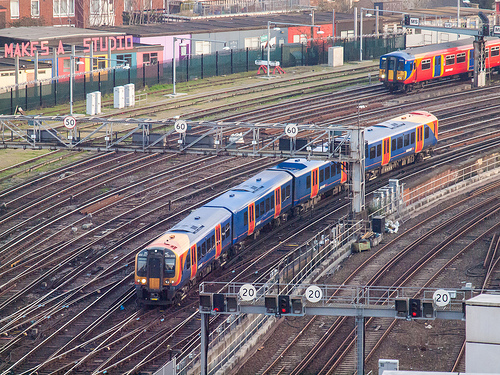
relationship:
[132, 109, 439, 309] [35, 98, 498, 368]
car on tracks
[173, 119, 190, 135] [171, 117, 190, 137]
number on sign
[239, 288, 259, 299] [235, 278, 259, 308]
20 on sign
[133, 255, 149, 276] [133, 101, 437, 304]
windshield on train